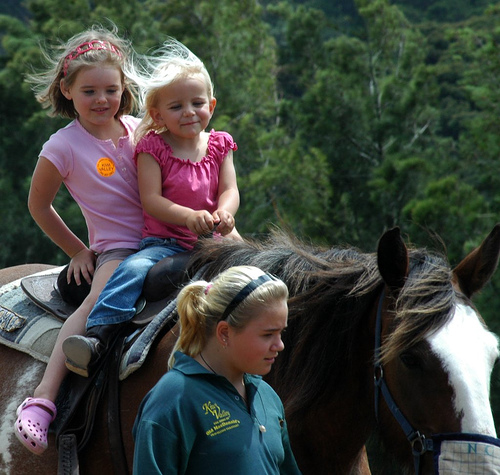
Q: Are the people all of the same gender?
A: Yes, all the people are female.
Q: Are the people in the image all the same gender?
A: Yes, all the people are female.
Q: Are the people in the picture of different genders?
A: No, all the people are female.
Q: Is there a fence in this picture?
A: No, there are no fences.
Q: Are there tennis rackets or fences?
A: No, there are no fences or tennis rackets.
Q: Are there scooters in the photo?
A: No, there are no scooters.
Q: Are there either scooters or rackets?
A: No, there are no scooters or rackets.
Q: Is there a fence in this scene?
A: No, there are no fences.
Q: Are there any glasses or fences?
A: No, there are no fences or glasses.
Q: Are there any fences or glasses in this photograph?
A: No, there are no fences or glasses.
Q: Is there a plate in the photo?
A: No, there are no plates.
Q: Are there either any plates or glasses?
A: No, there are no plates or glasses.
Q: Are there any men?
A: No, there are no men.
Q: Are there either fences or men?
A: No, there are no men or fences.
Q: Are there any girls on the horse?
A: Yes, there is a girl on the horse.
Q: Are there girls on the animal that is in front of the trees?
A: Yes, there is a girl on the horse.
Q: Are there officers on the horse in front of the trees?
A: No, there is a girl on the horse.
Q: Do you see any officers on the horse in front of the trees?
A: No, there is a girl on the horse.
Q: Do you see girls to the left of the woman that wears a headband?
A: Yes, there is a girl to the left of the woman.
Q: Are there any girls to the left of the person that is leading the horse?
A: Yes, there is a girl to the left of the woman.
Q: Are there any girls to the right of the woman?
A: No, the girl is to the left of the woman.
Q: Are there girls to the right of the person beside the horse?
A: No, the girl is to the left of the woman.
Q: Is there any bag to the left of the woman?
A: No, there is a girl to the left of the woman.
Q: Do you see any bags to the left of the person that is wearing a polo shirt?
A: No, there is a girl to the left of the woman.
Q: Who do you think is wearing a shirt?
A: The girl is wearing a shirt.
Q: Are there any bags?
A: No, there are no bags.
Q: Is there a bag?
A: No, there are no bags.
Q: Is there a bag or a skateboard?
A: No, there are no bags or skateboards.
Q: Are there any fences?
A: No, there are no fences.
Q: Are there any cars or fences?
A: No, there are no fences or cars.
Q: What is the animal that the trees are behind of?
A: The animal is a horse.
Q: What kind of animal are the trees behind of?
A: The trees are behind the horse.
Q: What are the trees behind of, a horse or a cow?
A: The trees are behind a horse.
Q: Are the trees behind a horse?
A: Yes, the trees are behind a horse.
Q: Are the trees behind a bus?
A: No, the trees are behind a horse.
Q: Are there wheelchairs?
A: No, there are no wheelchairs.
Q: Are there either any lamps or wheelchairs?
A: No, there are no wheelchairs or lamps.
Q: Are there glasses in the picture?
A: No, there are no glasses.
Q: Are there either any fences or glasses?
A: No, there are no glasses or fences.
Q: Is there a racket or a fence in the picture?
A: No, there are no fences or rackets.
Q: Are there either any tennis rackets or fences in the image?
A: No, there are no fences or tennis rackets.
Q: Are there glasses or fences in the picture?
A: No, there are no glasses or fences.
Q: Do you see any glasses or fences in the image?
A: No, there are no glasses or fences.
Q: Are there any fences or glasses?
A: No, there are no glasses or fences.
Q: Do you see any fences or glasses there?
A: No, there are no glasses or fences.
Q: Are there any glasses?
A: No, there are no glasses.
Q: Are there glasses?
A: No, there are no glasses.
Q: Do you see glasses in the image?
A: No, there are no glasses.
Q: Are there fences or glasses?
A: No, there are no glasses or fences.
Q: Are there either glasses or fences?
A: No, there are no glasses or fences.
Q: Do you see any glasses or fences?
A: No, there are no glasses or fences.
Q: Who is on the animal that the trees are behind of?
A: The girl is on the horse.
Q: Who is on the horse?
A: The girl is on the horse.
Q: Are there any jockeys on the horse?
A: No, there is a girl on the horse.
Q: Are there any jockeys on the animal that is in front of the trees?
A: No, there is a girl on the horse.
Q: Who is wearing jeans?
A: The girl is wearing jeans.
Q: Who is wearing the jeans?
A: The girl is wearing jeans.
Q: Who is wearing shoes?
A: The girl is wearing shoes.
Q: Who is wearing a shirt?
A: The girl is wearing a shirt.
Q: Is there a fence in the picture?
A: No, there are no fences.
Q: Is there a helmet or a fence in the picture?
A: No, there are no fences or helmets.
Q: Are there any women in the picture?
A: Yes, there is a woman.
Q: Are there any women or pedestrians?
A: Yes, there is a woman.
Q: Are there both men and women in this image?
A: No, there is a woman but no men.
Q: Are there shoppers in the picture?
A: No, there are no shoppers.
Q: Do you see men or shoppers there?
A: No, there are no shoppers or men.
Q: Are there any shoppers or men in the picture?
A: No, there are no shoppers or men.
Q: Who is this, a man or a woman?
A: This is a woman.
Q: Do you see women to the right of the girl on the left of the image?
A: Yes, there is a woman to the right of the girl.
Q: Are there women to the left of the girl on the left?
A: No, the woman is to the right of the girl.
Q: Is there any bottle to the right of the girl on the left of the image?
A: No, there is a woman to the right of the girl.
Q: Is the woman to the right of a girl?
A: Yes, the woman is to the right of a girl.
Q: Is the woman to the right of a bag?
A: No, the woman is to the right of a girl.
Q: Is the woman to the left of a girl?
A: No, the woman is to the right of a girl.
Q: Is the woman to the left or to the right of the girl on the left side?
A: The woman is to the right of the girl.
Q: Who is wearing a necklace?
A: The woman is wearing a necklace.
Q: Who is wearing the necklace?
A: The woman is wearing a necklace.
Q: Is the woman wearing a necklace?
A: Yes, the woman is wearing a necklace.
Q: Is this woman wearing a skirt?
A: No, the woman is wearing a necklace.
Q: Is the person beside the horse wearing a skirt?
A: No, the woman is wearing a necklace.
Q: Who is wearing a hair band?
A: The woman is wearing a hair band.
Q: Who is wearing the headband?
A: The woman is wearing a hair band.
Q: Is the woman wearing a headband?
A: Yes, the woman is wearing a headband.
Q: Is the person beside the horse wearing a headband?
A: Yes, the woman is wearing a headband.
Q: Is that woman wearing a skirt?
A: No, the woman is wearing a headband.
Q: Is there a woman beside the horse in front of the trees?
A: Yes, there is a woman beside the horse.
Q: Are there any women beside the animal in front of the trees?
A: Yes, there is a woman beside the horse.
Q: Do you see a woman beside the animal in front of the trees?
A: Yes, there is a woman beside the horse.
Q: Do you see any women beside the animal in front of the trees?
A: Yes, there is a woman beside the horse.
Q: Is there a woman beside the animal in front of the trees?
A: Yes, there is a woman beside the horse.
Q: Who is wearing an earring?
A: The woman is wearing an earring.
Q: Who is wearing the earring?
A: The woman is wearing an earring.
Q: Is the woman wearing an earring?
A: Yes, the woman is wearing an earring.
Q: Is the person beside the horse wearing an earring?
A: Yes, the woman is wearing an earring.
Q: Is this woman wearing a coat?
A: No, the woman is wearing an earring.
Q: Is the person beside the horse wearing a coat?
A: No, the woman is wearing an earring.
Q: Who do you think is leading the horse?
A: The woman is leading the horse.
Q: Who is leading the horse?
A: The woman is leading the horse.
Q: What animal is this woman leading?
A: The woman is leading the horse.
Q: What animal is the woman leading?
A: The woman is leading the horse.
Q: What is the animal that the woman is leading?
A: The animal is a horse.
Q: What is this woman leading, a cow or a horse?
A: The woman is leading a horse.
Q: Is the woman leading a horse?
A: Yes, the woman is leading a horse.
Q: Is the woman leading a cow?
A: No, the woman is leading a horse.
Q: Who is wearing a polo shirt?
A: The woman is wearing a polo shirt.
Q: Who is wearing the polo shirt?
A: The woman is wearing a polo shirt.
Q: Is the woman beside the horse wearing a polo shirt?
A: Yes, the woman is wearing a polo shirt.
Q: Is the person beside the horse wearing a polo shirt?
A: Yes, the woman is wearing a polo shirt.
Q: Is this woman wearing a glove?
A: No, the woman is wearing a polo shirt.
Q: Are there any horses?
A: Yes, there is a horse.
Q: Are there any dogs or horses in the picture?
A: Yes, there is a horse.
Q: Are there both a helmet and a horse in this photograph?
A: No, there is a horse but no helmets.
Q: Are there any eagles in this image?
A: No, there are no eagles.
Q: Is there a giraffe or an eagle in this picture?
A: No, there are no eagles or giraffes.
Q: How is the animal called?
A: The animal is a horse.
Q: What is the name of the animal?
A: The animal is a horse.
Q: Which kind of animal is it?
A: The animal is a horse.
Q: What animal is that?
A: This is a horse.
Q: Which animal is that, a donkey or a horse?
A: This is a horse.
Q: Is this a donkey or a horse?
A: This is a horse.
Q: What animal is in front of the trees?
A: The horse is in front of the trees.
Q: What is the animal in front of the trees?
A: The animal is a horse.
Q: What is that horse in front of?
A: The horse is in front of the trees.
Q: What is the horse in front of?
A: The horse is in front of the trees.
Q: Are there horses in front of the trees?
A: Yes, there is a horse in front of the trees.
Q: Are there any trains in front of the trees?
A: No, there is a horse in front of the trees.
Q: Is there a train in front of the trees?
A: No, there is a horse in front of the trees.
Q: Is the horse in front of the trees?
A: Yes, the horse is in front of the trees.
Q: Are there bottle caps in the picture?
A: No, there are no bottle caps.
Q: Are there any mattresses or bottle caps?
A: No, there are no bottle caps or mattresses.